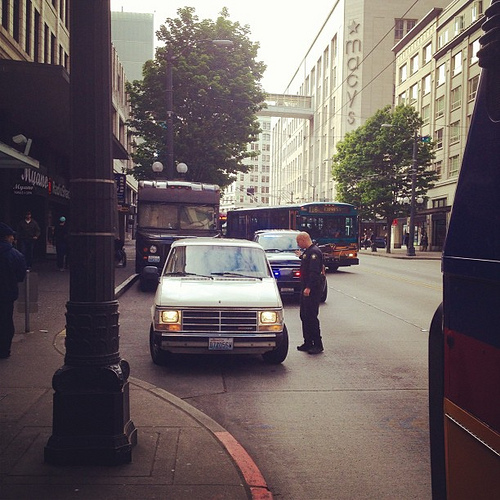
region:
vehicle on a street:
[137, 228, 299, 377]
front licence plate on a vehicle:
[203, 330, 239, 358]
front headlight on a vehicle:
[154, 298, 189, 330]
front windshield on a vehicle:
[159, 241, 279, 286]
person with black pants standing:
[287, 226, 334, 363]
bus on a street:
[221, 198, 367, 275]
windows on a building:
[433, 61, 447, 126]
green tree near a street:
[326, 91, 438, 263]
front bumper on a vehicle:
[147, 325, 288, 355]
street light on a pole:
[146, 156, 195, 177]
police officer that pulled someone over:
[291, 227, 330, 358]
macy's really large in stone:
[342, 18, 363, 128]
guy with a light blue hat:
[50, 211, 71, 271]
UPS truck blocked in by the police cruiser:
[131, 176, 216, 286]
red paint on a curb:
[212, 425, 269, 495]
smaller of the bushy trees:
[325, 97, 440, 217]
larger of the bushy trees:
[120, 1, 266, 186]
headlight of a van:
[155, 305, 275, 325]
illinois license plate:
[205, 334, 235, 352]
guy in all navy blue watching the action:
[0, 222, 29, 362]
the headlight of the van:
[159, 310, 176, 324]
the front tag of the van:
[208, 335, 236, 351]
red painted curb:
[218, 430, 274, 499]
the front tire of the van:
[272, 333, 287, 358]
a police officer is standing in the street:
[291, 234, 333, 349]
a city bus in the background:
[282, 200, 354, 224]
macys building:
[346, 25, 368, 128]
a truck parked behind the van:
[135, 179, 222, 224]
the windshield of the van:
[174, 249, 247, 278]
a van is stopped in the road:
[155, 244, 294, 368]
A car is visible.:
[145, 225, 300, 394]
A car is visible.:
[153, 183, 362, 437]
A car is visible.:
[147, 251, 229, 347]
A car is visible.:
[177, 238, 259, 363]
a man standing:
[289, 229, 336, 355]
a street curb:
[200, 414, 260, 489]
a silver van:
[137, 232, 299, 369]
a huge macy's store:
[280, 7, 406, 122]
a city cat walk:
[232, 82, 326, 122]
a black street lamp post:
[35, 10, 137, 457]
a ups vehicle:
[130, 177, 229, 283]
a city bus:
[223, 198, 370, 266]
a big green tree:
[115, 5, 277, 195]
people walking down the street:
[13, 207, 102, 269]